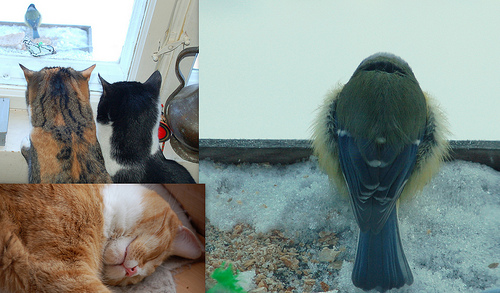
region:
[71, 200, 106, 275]
the cat is sleeping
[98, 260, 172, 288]
the cat is sleeping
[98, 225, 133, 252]
the cat is sleeping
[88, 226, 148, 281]
the cat is sleeping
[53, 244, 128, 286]
the cat is sleeping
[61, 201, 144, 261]
the cat is sleeping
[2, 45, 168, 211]
Cats looking out the window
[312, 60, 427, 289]
Bird sitting on edge of gutter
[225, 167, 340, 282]
Snow on the roof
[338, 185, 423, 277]
Birds tail covered in feathers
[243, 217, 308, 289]
Seeds on the snow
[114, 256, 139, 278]
Pink nose on the cat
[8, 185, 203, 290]
Orange cat sleeping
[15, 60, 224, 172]
Cats watching the bird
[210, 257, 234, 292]
Green feather laying in snow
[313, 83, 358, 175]
Fluffy bird on wings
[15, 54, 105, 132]
the head of a cat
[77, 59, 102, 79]
a brown cat's ear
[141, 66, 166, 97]
a black cat's ear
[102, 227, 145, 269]
the mouth of a cat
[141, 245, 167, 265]
the eye of a cat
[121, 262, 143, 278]
the nose of a cat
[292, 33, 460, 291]
a bird on the ground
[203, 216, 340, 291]
rocks on the ground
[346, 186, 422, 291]
the tail of a bird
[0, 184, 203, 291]
a sleeping cat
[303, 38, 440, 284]
Bird facing away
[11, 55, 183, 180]
Two cats watching bird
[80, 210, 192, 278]
Cat's eyes are closed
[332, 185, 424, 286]
Tail of bird is blue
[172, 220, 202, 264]
Right ear of kitty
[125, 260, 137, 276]
Cat's nose is pink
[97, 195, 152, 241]
White patch on cat's neck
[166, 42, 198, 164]
Kettle nearby cat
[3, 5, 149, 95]
Window near cats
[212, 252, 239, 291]
Green furry object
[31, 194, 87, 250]
dark orange kitten fur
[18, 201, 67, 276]
dark orange kitten fur